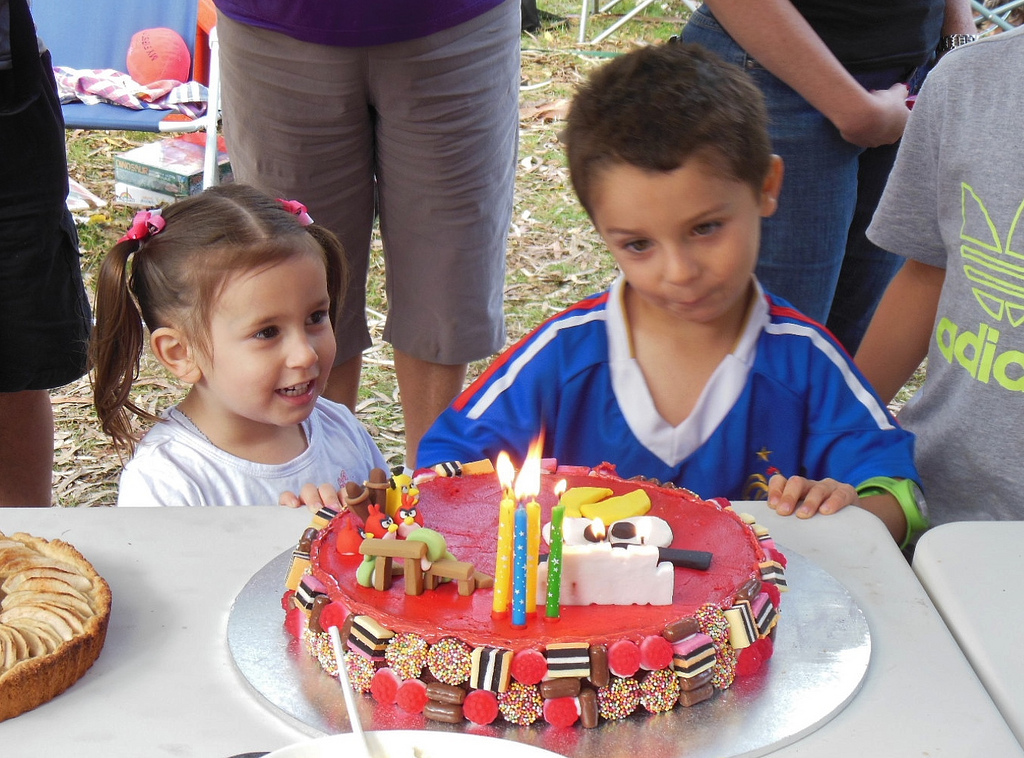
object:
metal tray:
[203, 505, 880, 758]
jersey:
[414, 271, 915, 486]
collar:
[594, 275, 772, 465]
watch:
[852, 465, 929, 556]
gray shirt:
[841, 24, 1021, 522]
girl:
[88, 182, 406, 503]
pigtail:
[299, 181, 345, 327]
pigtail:
[80, 209, 168, 448]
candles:
[542, 470, 566, 623]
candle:
[510, 429, 529, 630]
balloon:
[124, 25, 192, 87]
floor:
[517, 1, 566, 310]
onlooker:
[210, 0, 525, 480]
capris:
[210, 1, 521, 370]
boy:
[408, 35, 928, 528]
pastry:
[0, 533, 115, 723]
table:
[0, 504, 1019, 755]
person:
[0, 0, 102, 505]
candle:
[525, 434, 542, 611]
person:
[632, 0, 993, 461]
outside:
[129, 14, 907, 448]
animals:
[391, 490, 427, 547]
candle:
[488, 449, 515, 616]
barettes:
[110, 207, 170, 245]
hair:
[94, 183, 348, 288]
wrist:
[796, 82, 879, 153]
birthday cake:
[257, 415, 802, 735]